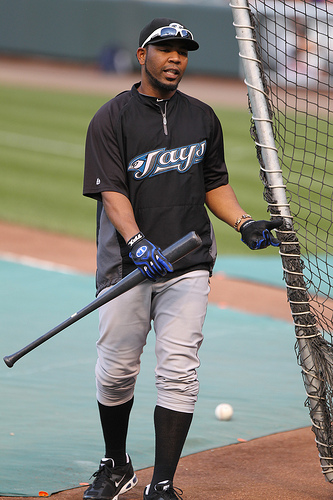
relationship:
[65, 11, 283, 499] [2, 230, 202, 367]
man holding baseball bat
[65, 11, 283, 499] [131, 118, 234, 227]
man wearing jersey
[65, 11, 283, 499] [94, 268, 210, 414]
man wearing shorts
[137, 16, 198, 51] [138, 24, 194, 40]
hat with glasses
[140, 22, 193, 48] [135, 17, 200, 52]
glasses resting on hat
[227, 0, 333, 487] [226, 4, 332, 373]
net on pole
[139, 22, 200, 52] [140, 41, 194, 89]
hat on head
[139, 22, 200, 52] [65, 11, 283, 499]
hat on man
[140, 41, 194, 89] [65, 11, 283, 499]
head on man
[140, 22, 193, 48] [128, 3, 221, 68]
glasses on hat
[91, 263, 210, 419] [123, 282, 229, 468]
shorts on legs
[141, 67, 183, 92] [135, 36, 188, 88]
beard on face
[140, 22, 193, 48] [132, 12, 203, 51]
glasses over hat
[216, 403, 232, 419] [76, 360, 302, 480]
baseball on ground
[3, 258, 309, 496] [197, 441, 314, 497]
tarp over ground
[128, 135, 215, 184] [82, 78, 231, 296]
logo on jersey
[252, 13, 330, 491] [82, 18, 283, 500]
net near man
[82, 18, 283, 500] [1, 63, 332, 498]
man walking to edge field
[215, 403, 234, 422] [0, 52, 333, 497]
baseball on ground